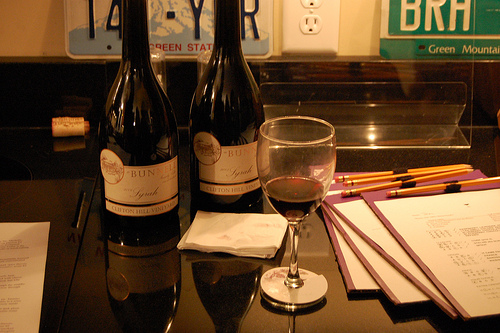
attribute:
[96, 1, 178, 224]
bottle — wine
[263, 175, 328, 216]
wine — glass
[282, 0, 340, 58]
receptacle — white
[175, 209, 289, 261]
napkins — white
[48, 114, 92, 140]
cork — off, brown, white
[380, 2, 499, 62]
license — green, hung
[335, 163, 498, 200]
pencils — yellow, sharpened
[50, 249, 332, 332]
black — shiny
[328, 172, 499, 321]
set — four